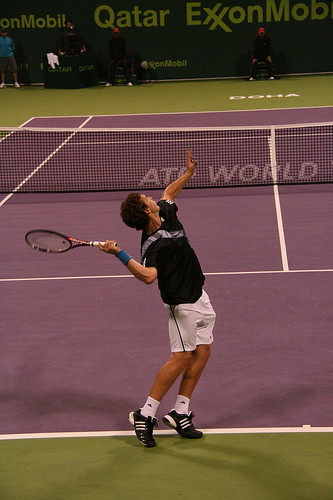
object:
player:
[98, 145, 218, 448]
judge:
[248, 26, 275, 82]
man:
[0, 26, 22, 89]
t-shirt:
[0, 36, 15, 59]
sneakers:
[127, 407, 161, 449]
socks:
[171, 392, 191, 417]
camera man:
[58, 18, 87, 57]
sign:
[0, 0, 332, 33]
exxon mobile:
[185, 0, 333, 34]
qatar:
[92, 4, 171, 31]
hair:
[119, 192, 150, 232]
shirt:
[138, 199, 206, 307]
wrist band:
[115, 248, 135, 267]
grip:
[89, 240, 118, 248]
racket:
[22, 228, 118, 254]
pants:
[162, 288, 218, 353]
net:
[0, 121, 333, 193]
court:
[0, 72, 333, 499]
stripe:
[169, 304, 186, 353]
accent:
[140, 229, 184, 262]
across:
[0, 121, 333, 192]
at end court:
[0, 63, 333, 96]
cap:
[258, 27, 265, 34]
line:
[0, 424, 333, 442]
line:
[33, 104, 333, 120]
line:
[271, 127, 291, 273]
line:
[0, 116, 95, 208]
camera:
[63, 23, 82, 57]